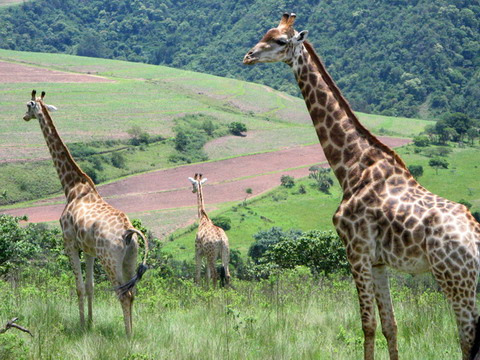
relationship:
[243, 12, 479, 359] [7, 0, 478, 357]
giraffe in field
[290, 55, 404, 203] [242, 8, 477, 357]
neck of giraffe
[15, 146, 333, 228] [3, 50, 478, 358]
path in field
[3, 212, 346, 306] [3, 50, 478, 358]
shrubbery in field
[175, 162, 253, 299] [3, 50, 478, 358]
giraffe looking down field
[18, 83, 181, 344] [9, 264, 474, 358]
giraffe standing in grass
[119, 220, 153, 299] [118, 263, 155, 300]
tail with hair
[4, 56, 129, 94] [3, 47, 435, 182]
area on top of hill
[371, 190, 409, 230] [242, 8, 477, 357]
spot on giraffe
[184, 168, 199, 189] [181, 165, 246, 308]
horn on head of giraffe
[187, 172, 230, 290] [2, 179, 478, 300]
giraffe looking down cliff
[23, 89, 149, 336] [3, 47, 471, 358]
giraffe looking across landscape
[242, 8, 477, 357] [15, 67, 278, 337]
giraffe gazing at companions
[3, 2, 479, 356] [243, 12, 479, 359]
savannah with giraffe